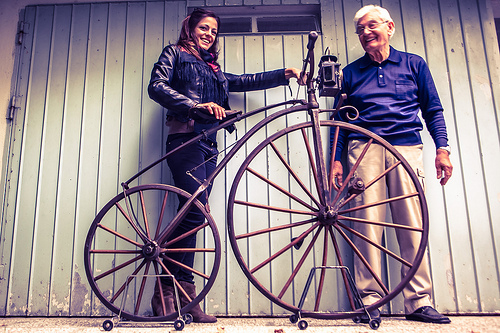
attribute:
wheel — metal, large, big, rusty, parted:
[243, 135, 409, 304]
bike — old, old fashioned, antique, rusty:
[135, 62, 417, 296]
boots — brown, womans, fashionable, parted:
[149, 263, 207, 323]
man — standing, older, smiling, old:
[335, 11, 444, 279]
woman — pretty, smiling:
[141, 17, 236, 289]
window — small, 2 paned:
[196, 6, 305, 32]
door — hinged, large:
[107, 40, 129, 78]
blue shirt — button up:
[365, 110, 375, 116]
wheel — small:
[104, 197, 209, 280]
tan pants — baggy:
[351, 143, 437, 297]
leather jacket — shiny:
[166, 48, 197, 83]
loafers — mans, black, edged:
[346, 296, 448, 331]